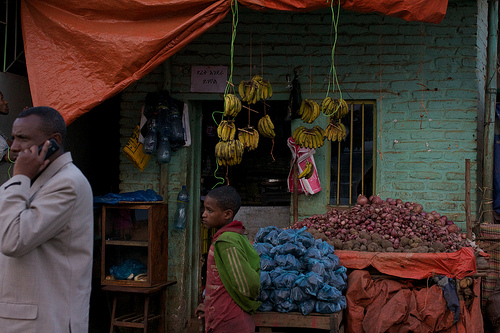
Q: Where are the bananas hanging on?
A: Vine.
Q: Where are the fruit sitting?
A: In stand.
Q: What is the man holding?
A: Phone.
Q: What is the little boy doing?
A: Standing.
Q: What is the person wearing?
A: Tan jacket.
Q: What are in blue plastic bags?
A: Pile of fruits.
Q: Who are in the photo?
A: Man and a boy.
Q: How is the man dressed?
A: In a tan suit jacket.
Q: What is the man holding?
A: Black cell phone.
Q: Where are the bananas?
A: Hanging on roof.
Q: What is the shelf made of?
A: Wood.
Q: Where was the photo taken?
A: Fruit stand.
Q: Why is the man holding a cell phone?
A: Talking through it.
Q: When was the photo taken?
A: Daylight.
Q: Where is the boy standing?
A: In front of building.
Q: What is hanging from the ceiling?
A: Bananas.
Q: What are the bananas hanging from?
A: Green string.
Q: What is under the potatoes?
A: Orange cloth.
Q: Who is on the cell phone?
A: Man in suit jacket.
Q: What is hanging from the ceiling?
A: Orange tarp.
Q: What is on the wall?
A: Green bricks.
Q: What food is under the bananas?
A: Red potatoes.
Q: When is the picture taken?
A: Daytime.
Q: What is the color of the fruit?
A: Yellow.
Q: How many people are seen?
A: Two.